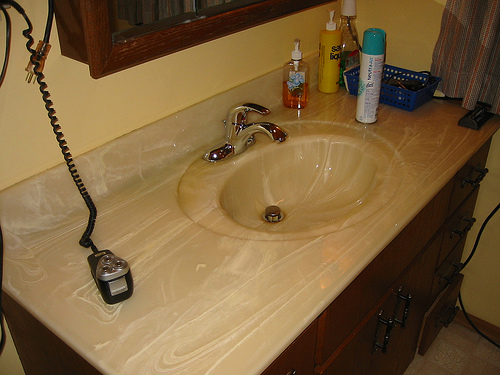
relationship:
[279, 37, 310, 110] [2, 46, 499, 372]
bottle on counter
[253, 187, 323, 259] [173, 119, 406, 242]
stopper in bathroom sink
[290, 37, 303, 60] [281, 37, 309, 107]
pump on bottle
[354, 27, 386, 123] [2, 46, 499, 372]
can on counter